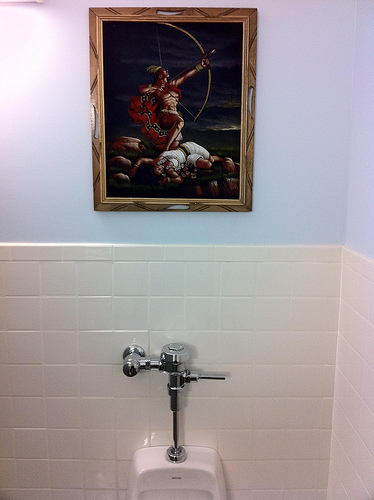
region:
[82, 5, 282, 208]
Picture above the toilet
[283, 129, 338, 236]
blue wall above tile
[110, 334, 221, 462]
metal toilet flushing mechainsm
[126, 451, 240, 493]
White porcelain urinal on wall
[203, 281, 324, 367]
White tile on wall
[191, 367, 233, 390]
Flush handle on toilet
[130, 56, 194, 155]
man with bow and arrow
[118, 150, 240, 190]
Fruit on the bottom of picture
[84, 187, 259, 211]
Brown frame of picture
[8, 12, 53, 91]
light cast on wall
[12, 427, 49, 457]
a tile on a wall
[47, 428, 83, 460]
a tile on a wall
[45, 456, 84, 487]
a tile on a wall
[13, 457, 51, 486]
a tile on a wall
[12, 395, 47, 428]
a tile on a wall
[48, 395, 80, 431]
a tile on a wall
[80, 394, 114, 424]
a tile on a wall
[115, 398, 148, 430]
a tile on a wall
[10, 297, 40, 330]
a tile on a wall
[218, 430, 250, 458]
a tile on a wall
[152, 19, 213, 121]
a bow and arrow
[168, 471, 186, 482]
writing on the urinal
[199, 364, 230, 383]
a metal flushing handle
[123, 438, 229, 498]
a white urinal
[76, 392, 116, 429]
a white wall tile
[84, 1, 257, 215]
a framed picture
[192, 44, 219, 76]
the hand of the man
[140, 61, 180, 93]
the head of the man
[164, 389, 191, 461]
a metal pipe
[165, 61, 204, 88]
the arm of the man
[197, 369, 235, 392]
handle of the urinal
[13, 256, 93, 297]
white tiles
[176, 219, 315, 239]
wall in the bathroom is blue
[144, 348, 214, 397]
chrome handles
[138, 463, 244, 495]
the urinal is porcelain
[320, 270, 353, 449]
A seam in the wall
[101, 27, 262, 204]
A picture on the wall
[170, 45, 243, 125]
A bow and arrow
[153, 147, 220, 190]
A dead woman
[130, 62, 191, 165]
A warrior holding a bow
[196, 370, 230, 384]
the flusher handle of the urinal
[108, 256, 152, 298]
a white tile on the wall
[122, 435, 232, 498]
a white porcelain urinal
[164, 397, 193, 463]
a metal pipe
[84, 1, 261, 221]
a painting on the wall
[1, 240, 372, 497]
a white tile wall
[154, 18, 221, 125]
a bow and arrow on the painting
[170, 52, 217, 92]
the arm of a man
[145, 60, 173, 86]
the head of a man